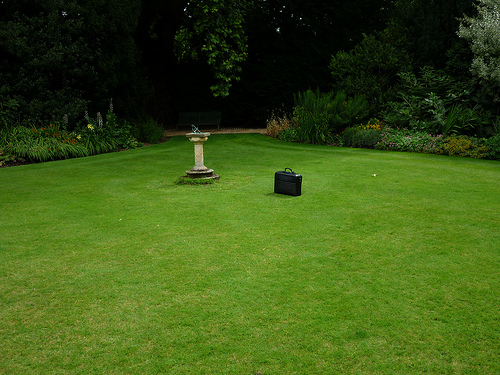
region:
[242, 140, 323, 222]
a suitcase on the grass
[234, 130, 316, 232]
the suitcase is black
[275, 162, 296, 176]
the suitcase has a handle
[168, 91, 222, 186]
this is a sundial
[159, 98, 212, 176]
the sundial is made of stone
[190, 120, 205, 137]
the dial is green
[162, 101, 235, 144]
there is a bench in the background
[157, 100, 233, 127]
the bench is in the shade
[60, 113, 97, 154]
the flowers are white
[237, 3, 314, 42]
the sky is showing to through the trees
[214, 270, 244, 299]
Small patch of smooth green grass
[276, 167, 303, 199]
Black case in the grass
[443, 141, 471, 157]
Yellow and green leaves in the bush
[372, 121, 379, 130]
Yellow flowers in the bush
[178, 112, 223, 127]
Green bench in the distance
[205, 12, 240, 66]
Green leaves on the tree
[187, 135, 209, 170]
Beige object in the grass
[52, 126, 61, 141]
Red flowers in the shrubs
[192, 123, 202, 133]
Green object on top of the beige object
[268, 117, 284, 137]
Brown leaves on the bush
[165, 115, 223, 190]
white birdbath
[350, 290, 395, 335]
patch of green grass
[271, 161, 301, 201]
black briefcase on the grass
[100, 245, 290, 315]
grassy area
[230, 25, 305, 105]
green leaves hanging down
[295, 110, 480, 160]
landscaped plants on the ground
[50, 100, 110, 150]
flowers on on the plants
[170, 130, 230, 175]
white column holding up the birdbath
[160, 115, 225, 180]
yard decoration on the lawn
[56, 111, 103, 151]
white flower bulbs on the plants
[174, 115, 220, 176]
bird feeder on green lawn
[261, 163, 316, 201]
suspicious briefcase in back yard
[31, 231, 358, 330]
freshly cut turf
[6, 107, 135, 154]
garden shrubbery in back yard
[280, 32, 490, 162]
lawn shrubbery decor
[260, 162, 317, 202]
black briefcase on freshly cut turf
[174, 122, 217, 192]
small bird feeder on green grass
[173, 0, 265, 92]
leaves hanging from a tree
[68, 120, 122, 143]
lonely yellow flower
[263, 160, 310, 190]
small briefcase on green lawn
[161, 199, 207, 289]
part of a field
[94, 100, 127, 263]
part of the grass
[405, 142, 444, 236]
part of the plantation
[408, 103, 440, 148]
edge of a bush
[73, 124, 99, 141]
edge of a flower bed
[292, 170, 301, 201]
edge of a bag